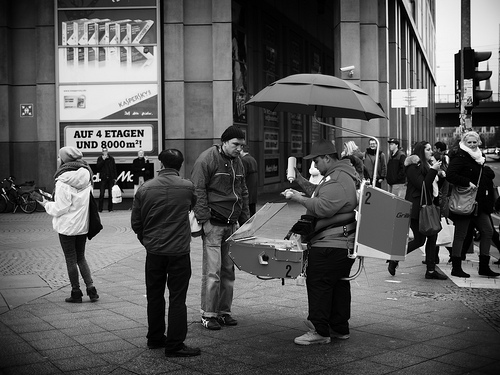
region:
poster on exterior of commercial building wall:
[51, 2, 168, 203]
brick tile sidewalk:
[18, 306, 102, 371]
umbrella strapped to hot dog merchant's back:
[239, 66, 388, 128]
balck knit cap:
[217, 120, 247, 144]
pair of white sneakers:
[294, 319, 351, 346]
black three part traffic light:
[451, 47, 494, 116]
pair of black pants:
[141, 250, 193, 348]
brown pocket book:
[446, 153, 486, 216]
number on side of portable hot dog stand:
[277, 259, 297, 279]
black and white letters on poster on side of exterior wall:
[63, 122, 157, 156]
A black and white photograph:
[0, 0, 499, 372]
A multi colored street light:
[452, 46, 492, 108]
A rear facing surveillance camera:
[340, 63, 357, 75]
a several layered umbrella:
[244, 70, 389, 122]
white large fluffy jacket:
[42, 167, 92, 235]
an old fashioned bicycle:
[0, 175, 42, 215]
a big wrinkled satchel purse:
[448, 158, 483, 214]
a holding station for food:
[227, 200, 313, 280]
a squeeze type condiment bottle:
[285, 156, 296, 184]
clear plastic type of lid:
[222, 197, 289, 242]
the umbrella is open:
[244, 39, 429, 163]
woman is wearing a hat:
[55, 141, 95, 175]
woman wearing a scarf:
[458, 123, 495, 171]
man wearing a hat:
[298, 132, 344, 180]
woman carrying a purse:
[403, 132, 449, 252]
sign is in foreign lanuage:
[57, 106, 157, 157]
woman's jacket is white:
[38, 171, 112, 240]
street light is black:
[446, 33, 497, 116]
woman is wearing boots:
[448, 230, 499, 290]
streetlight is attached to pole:
[448, 3, 495, 139]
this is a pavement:
[45, 309, 117, 374]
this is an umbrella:
[249, 74, 385, 119]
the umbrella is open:
[248, 81, 378, 126]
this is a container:
[285, 157, 295, 182]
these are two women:
[405, 143, 499, 267]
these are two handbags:
[424, 178, 471, 228]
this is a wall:
[13, 95, 60, 166]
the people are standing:
[143, 100, 259, 352]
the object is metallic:
[354, 175, 412, 262]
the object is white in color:
[61, 201, 79, 233]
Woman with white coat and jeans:
[17, 132, 142, 312]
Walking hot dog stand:
[209, 25, 434, 341]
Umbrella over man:
[230, 15, 396, 210]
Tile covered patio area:
[4, 287, 156, 356]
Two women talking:
[388, 126, 498, 255]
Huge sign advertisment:
[39, 5, 176, 167]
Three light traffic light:
[454, 47, 499, 110]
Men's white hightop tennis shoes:
[285, 304, 377, 368]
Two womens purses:
[417, 172, 492, 240]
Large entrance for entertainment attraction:
[228, 22, 336, 191]